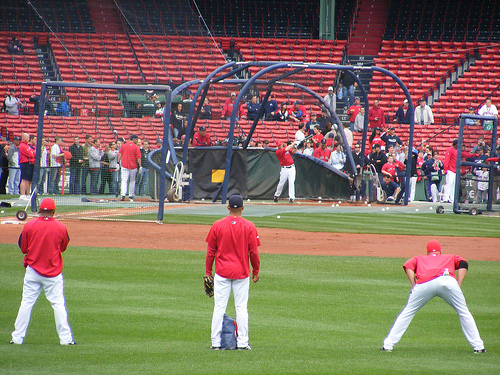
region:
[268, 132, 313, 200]
the batter swings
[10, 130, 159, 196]
a crowd watches on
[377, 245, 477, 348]
a man ready to move toward the ball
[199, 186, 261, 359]
a man waiting for practice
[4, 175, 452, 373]
three men in uniform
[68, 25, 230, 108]
the bleachers are red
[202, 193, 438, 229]
several baseballs on the field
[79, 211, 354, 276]
nice clean looking dirt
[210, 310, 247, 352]
a man has a blue bag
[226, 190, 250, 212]
a black baseball cap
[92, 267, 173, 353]
Green grass on the field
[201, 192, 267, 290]
Player wearing a red shirt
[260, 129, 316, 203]
Baseball player swinging the bat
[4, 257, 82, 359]
White pants on player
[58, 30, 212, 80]
Many empty red seats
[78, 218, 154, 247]
Brown dirt on the field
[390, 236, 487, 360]
Baseball player bending over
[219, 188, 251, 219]
Black hat on player's head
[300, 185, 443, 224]
Many white baseballs on the ground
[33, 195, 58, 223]
A red hat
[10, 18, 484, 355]
baseball players warming up for a game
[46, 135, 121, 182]
fans in line to get in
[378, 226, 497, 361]
a player bending over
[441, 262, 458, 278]
a bottle of water in a pocket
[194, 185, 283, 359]
a player wearing a blue cap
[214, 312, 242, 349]
a blue bag on the ground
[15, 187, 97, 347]
a player wearing a red cap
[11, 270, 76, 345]
white pants on a bottom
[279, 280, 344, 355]
thick green grass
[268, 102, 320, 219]
a player swinging his bat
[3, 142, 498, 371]
men on a baseball field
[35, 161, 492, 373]
men standing on basebal field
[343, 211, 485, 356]
a man bent over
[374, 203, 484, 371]
a man bent forward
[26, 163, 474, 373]
men wearing a hat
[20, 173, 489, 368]
three men on a baseball field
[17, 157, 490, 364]
three men wearing a hat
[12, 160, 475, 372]
three men wearing baseball hat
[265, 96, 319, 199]
a man batting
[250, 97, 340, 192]
a man swinging bat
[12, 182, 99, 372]
man wearing a red and white baseball jersey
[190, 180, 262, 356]
man wearing a red and white baseball jersey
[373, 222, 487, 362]
man wearing a red and white baseball jersey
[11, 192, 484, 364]
three men wearing red and white baseball jerseys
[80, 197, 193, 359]
dirt and grass baseball field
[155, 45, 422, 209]
metal frame above a baseball batter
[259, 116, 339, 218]
man wearing a red and white baseball jersey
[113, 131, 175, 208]
man wearing a red and white baseball jersey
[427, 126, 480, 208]
man wearing a red and white baseball jersey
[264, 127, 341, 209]
man swinging a baseball bat